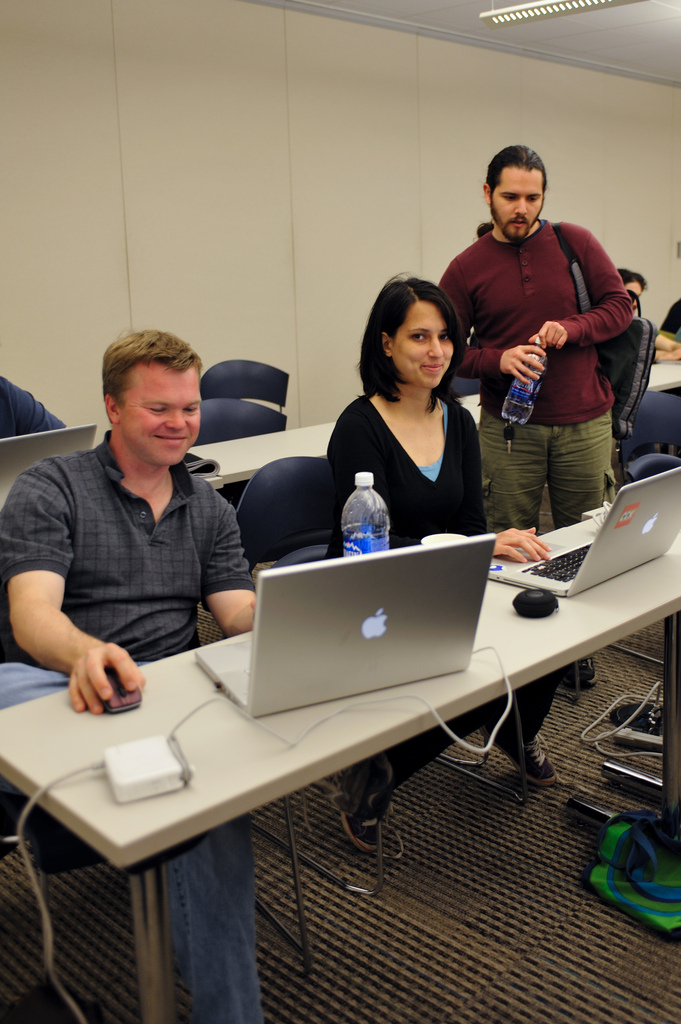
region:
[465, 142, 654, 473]
man in burgundy shirt and green pants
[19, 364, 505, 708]
man smiling while on laptop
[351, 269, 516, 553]
woman in black and blue shirt smiling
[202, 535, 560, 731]
laptop with apple symbol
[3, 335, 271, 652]
man with grey shirt smiling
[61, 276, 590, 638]
man and woman smiling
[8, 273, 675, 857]
man and woman sitting at table with laptops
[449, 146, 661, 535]
man in burgundy shirt holding water bottle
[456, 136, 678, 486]
man in burgundy shirt and green pants with black backpack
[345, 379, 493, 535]
woman wearing a black shirt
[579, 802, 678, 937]
green bag on the floor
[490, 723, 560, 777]
woman wearing purple shoes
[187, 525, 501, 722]
laptop on the table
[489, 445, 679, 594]
laptop on the table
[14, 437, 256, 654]
man wearing a grey shirt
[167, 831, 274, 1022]
man wearing blue jeans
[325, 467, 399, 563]
water bottle on the table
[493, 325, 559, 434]
man holding a water bottle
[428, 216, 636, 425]
man wearing red shirt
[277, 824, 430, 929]
silver legs on the chair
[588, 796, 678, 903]
green bag with blue border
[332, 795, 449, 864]
white laces in sneakers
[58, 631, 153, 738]
purple mouse in man's hand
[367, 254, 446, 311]
part in woman's hair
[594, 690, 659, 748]
large electrical socket on the ground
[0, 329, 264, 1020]
man is sitting at table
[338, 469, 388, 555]
water bottle is sitting on table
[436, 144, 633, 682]
man is holding water bottle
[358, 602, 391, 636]
lit up apple is on the back of computer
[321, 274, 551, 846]
lady is sitting at table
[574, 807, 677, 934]
green and blue bag is on the floor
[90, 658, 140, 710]
mouse is red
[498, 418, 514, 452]
key is attached to mans belt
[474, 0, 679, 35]
light is attached to the ceiling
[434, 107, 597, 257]
head of a man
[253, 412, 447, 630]
bottle next to laptop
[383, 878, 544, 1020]
floor in the room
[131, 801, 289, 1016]
blue pant leg on person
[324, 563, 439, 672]
logo on the laptop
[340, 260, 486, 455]
woman looking at camera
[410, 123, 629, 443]
man holding a bottle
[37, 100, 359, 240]
wall behind the people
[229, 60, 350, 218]
line on the wall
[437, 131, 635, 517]
man with a water bottle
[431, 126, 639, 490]
Man in red shirt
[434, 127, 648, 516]
Man with water bottle wearing red shirt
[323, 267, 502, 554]
woman wearing black sweater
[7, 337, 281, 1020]
a person is sitting down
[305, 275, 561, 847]
a person is sitting down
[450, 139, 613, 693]
a person is standing up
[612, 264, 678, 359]
a person is sitting down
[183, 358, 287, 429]
a chair that you sit in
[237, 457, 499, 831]
a chair that you sit in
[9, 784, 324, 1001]
a chair that you sit in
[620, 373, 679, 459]
a chair that you sit in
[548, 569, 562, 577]
a key on a keyboard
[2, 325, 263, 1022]
man using a red computer mouse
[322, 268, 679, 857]
woman sitting in front of a laptop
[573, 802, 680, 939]
green and blue bag on the floor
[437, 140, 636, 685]
man holding a water bottle